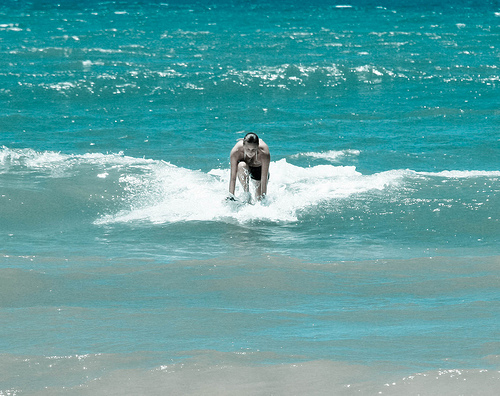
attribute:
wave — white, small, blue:
[44, 134, 403, 249]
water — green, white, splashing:
[25, 69, 447, 217]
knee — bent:
[232, 158, 263, 180]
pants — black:
[244, 157, 267, 188]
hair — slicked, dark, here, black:
[239, 123, 260, 155]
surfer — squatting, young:
[214, 118, 285, 216]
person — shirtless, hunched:
[223, 120, 295, 201]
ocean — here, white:
[293, 195, 461, 362]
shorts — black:
[230, 169, 288, 181]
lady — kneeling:
[213, 126, 326, 254]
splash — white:
[149, 161, 214, 226]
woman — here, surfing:
[231, 134, 271, 200]